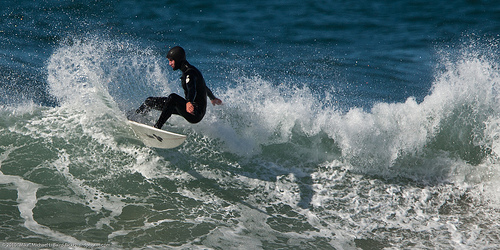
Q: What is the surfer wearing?
A: Wetsuit.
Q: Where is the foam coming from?
A: Water.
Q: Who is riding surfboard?
A: A man.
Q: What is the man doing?
A: Surfing.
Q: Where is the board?
A: In water.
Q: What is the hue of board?
A: White.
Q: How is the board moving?
A: Water wave.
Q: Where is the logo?
A: Wetsuit.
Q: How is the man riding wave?
A: Sideways.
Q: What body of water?
A: Ocean.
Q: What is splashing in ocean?
A: Water.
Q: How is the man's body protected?
A: With a wetsuit.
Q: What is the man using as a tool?
A: Surfboard.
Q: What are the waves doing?
A: Splashing.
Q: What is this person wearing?
A: A wet suit.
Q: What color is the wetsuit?
A: Black.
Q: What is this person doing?
A: Surfing.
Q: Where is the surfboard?
A: Under the surfer's feet.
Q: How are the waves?
A: White.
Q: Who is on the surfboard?
A: The surfer.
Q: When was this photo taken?
A: During the daytime.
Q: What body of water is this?
A: The ocean.